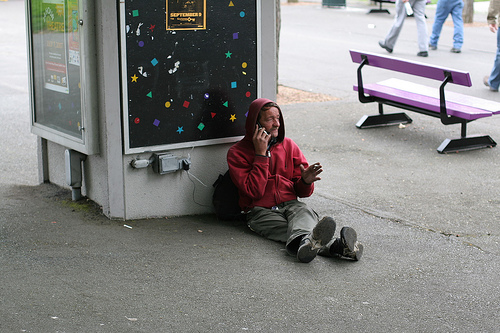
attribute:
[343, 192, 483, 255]
crack — large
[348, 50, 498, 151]
bench — purple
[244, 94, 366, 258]
man — wearing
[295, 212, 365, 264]
shoes — black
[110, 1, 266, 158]
post — large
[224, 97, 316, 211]
hoodie — red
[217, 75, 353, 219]
man — holding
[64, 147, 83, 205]
post — gray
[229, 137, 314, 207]
jacket — red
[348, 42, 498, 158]
bench — purple 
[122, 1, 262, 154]
poster — black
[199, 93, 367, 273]
man — wearing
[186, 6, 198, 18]
letter — written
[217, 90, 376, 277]
man — holding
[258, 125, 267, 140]
cellphone — silver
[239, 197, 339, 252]
pants — grey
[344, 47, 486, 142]
bench — purple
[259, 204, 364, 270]
pants — olive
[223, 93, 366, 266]
man — sitting, against, wearing, homeless